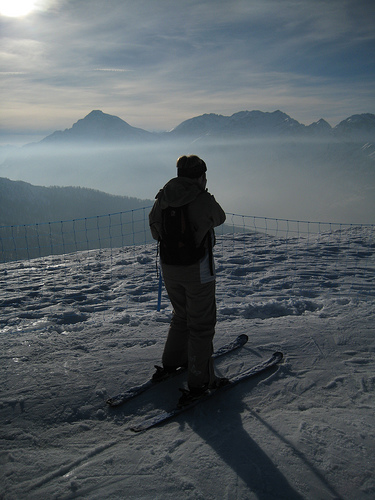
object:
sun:
[0, 0, 45, 30]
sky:
[0, 1, 372, 129]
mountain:
[21, 108, 375, 147]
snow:
[2, 227, 372, 499]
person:
[147, 155, 226, 394]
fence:
[1, 214, 374, 273]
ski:
[108, 333, 283, 434]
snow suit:
[147, 181, 226, 387]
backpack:
[157, 189, 216, 266]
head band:
[175, 162, 205, 176]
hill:
[3, 176, 373, 498]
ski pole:
[157, 269, 163, 312]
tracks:
[3, 384, 164, 499]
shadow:
[153, 373, 353, 499]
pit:
[236, 303, 294, 319]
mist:
[0, 134, 374, 226]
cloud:
[2, 2, 375, 129]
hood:
[154, 179, 200, 205]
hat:
[175, 153, 208, 180]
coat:
[148, 178, 226, 259]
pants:
[160, 256, 219, 377]